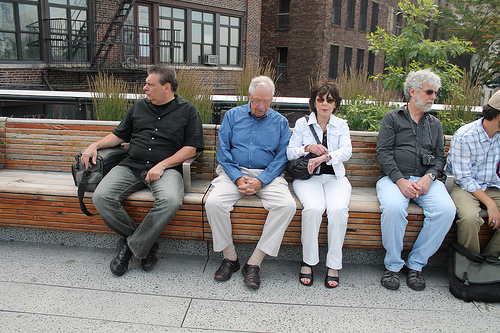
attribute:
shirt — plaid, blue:
[445, 118, 498, 193]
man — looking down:
[197, 72, 294, 284]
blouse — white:
[288, 111, 348, 172]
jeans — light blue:
[375, 173, 459, 278]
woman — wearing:
[288, 80, 353, 292]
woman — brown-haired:
[286, 78, 358, 288]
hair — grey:
[399, 67, 441, 91]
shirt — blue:
[376, 109, 445, 177]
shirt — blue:
[114, 98, 205, 173]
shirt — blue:
[284, 113, 354, 173]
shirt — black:
[101, 92, 210, 174]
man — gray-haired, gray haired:
[376, 67, 457, 290]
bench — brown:
[0, 117, 498, 249]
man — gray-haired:
[75, 63, 205, 280]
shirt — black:
[94, 89, 214, 180]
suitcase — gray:
[64, 140, 126, 206]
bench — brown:
[3, 118, 76, 231]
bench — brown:
[352, 133, 377, 250]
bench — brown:
[354, 187, 374, 213]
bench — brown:
[9, 170, 71, 191]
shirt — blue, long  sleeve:
[217, 104, 292, 192]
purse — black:
[286, 113, 323, 178]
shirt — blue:
[217, 105, 294, 183]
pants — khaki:
[207, 163, 295, 255]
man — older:
[205, 67, 300, 293]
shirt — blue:
[215, 97, 290, 187]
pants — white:
[297, 175, 349, 272]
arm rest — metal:
[180, 145, 203, 192]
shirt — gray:
[373, 104, 447, 183]